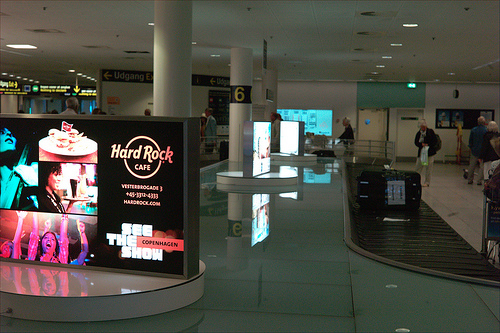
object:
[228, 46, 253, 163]
pole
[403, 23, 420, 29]
light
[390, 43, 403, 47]
light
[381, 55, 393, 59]
light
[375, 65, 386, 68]
light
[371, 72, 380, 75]
light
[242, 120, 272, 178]
sign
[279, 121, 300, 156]
sign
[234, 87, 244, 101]
6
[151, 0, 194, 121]
pole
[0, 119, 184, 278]
sign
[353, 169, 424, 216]
luggage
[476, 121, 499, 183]
woman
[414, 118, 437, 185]
person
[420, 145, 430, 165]
white bag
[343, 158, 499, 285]
conveyor belt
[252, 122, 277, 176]
sign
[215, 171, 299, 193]
podium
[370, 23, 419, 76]
lights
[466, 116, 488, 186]
man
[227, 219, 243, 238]
reflection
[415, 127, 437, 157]
black coat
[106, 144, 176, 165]
hard rock cafe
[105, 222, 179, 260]
see the show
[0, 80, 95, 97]
information signs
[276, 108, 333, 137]
sign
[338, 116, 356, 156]
person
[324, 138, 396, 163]
railing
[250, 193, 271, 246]
reflection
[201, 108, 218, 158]
people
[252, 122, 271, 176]
advertising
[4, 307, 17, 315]
outlet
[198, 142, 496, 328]
floor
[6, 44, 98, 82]
lights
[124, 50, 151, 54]
vent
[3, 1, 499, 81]
ceiling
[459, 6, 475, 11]
sprinkler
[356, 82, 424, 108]
awning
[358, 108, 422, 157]
doors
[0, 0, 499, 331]
airport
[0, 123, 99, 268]
pictures